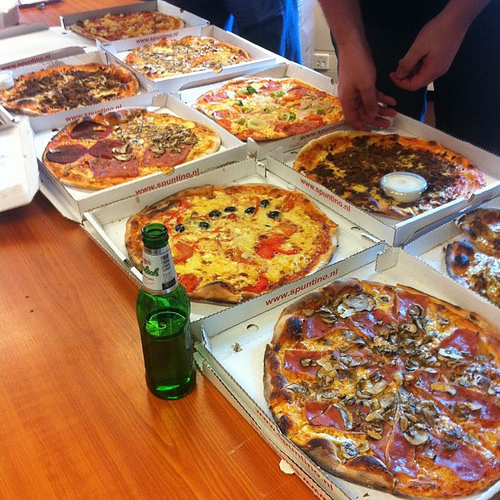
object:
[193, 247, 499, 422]
boxes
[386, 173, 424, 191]
blue cheese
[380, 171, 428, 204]
container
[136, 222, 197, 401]
beer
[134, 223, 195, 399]
bottle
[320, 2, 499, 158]
persons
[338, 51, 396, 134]
hand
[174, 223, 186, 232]
black olives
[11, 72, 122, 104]
sausage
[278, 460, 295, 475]
tap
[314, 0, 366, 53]
wall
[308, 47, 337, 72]
outlet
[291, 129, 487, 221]
pizza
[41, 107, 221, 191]
pizza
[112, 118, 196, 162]
mushrooms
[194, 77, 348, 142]
pizza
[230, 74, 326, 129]
bell pepper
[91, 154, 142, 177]
ham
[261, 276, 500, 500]
pizza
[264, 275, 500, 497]
burnt crust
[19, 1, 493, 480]
pizzas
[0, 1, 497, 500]
nine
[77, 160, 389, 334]
pizza box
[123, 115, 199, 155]
toppings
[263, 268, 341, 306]
address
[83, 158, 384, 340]
box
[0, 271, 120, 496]
table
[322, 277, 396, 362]
slice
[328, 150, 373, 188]
sauce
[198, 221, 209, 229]
black toppings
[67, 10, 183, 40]
pizza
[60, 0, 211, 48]
box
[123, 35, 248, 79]
pizza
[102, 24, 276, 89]
box\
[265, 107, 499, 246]
box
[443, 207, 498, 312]
pizza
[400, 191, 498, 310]
box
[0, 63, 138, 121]
pizza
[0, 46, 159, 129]
box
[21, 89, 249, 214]
box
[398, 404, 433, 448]
mushrooms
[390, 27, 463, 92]
hands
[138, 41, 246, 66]
cheese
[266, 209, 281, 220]
black olives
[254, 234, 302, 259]
pieces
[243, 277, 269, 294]
tomato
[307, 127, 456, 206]
sausage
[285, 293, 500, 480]
pepperoni